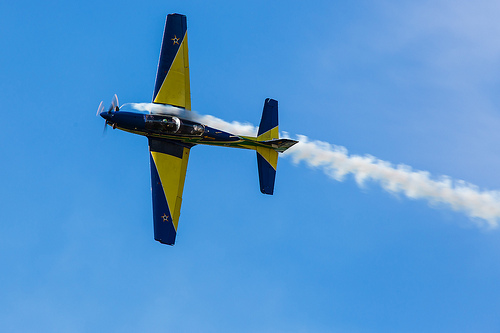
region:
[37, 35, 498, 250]
picture taken outdoors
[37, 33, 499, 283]
picture taken during the day time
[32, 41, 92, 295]
the sky is bright blue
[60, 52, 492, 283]
no clouds in the sky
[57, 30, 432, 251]
an airplane is in the sky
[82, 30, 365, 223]
the plane is blue and yellow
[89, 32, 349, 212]
the plane is pitched on its side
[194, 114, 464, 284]
the plane has a trail of smoke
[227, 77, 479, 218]
the smoke is white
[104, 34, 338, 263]
the plane is a stunt plane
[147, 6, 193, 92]
the wing of a plane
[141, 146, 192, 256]
the wing of a plane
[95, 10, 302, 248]
An airplane jet flying sideways.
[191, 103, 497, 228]
A grey smoke produced by the engine.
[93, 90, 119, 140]
The helixes that are making the plane fly.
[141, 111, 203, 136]
The two available seats on the plane.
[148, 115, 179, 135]
The seat in which the pilot is sitting.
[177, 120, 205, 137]
A seat used for one passenger.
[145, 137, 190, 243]
The left wing attached on the plane.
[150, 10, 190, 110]
The right wing of the plane is blue and yellow.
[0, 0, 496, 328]
The big blue sky above the plane.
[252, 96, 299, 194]
The tail of a beautiful airplane.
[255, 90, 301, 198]
the tail of a plane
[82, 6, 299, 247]
a plane in the sky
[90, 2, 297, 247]
a colored plane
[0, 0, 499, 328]
the blue clear sky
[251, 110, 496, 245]
smoke from the plane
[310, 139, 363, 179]
white smoke in the sky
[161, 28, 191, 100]
yellow paint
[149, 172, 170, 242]
blue paint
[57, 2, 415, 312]
a plane in the sky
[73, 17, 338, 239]
this plane is blue and yellow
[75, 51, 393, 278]
white smoke from plane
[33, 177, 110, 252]
the sky is clear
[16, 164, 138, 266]
the sky is blue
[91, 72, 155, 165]
the plane's propeller is spinning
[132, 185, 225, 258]
the yellow star on the wing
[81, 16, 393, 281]
the plane at an airshow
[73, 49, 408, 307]
a plane doing skywriting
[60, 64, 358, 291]
blue and yellow plane